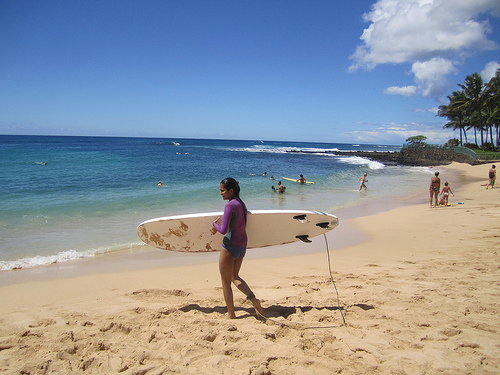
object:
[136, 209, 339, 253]
board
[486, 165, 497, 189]
person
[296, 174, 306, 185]
person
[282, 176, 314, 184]
surfboard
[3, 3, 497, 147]
sky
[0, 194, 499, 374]
ground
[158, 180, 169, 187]
person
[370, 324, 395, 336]
footprints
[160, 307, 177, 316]
footprints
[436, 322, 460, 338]
footprints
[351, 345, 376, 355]
footprints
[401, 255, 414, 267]
footprints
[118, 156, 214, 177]
waves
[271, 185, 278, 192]
people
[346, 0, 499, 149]
clouds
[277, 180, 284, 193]
people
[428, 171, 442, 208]
people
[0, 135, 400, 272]
ocean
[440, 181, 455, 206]
child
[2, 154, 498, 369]
shore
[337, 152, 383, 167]
wave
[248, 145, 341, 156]
wave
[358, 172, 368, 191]
people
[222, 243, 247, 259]
bikini bottoms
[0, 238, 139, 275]
wave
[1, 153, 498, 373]
beach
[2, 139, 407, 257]
water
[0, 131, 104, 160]
distant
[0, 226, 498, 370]
sand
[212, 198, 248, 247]
top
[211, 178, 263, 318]
girl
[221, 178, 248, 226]
hair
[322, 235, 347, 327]
string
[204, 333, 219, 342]
footprints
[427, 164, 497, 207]
three